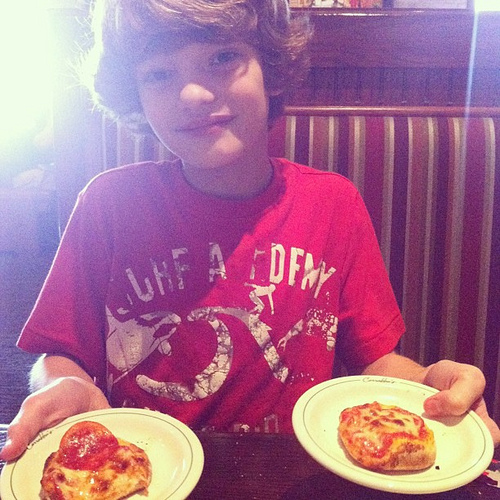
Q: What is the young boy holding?
A: Two saucers.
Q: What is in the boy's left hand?
A: A white plate.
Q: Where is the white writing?
A: On the red t-shirt.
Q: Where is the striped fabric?
A: On the back of the booth.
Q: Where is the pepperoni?
A: On the pizza.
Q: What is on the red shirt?
A: A white design with writing.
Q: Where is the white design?
A: On the t-shirt.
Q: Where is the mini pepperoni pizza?
A: On the plate.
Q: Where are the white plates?
A: In the boy's hands.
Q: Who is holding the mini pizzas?
A: The boy.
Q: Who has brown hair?
A: The boy.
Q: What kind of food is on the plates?
A: Pizza.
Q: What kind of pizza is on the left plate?
A: Pepperoni.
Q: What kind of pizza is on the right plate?
A: Cheese.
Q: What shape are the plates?
A: Round.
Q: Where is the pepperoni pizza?
A: On the left plate.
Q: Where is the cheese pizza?
A: On the right plate.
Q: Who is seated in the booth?
A: A young boy.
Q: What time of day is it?
A: Afternoon.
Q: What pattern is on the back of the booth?
A: Stripes.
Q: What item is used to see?
A: Eyes.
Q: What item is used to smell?
A: A nose.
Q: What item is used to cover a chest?
A: A shirt.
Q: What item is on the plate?
A: A pizza.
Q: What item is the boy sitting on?
A: A chair.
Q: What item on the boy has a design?
A: A shirt.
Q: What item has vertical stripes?
A: A chair.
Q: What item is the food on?
A: A plate.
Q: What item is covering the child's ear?
A: The ear.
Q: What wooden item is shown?
A: A table.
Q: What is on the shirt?
A: White writing on red shirt.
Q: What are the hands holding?
A: Hands holding white plates.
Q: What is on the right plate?
A: A mini personal cheese pizza.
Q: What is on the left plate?
A: A mini personal pepperoni pizza.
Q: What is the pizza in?
A: A small white shallow bowl with a stripe.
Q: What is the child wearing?
A: A child's red shirt with a picture of a shark and surfer.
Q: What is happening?
A: A young boy posing for a picture with two mini pizzas.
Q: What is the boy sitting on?
A: A stripped booth seat.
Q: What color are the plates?
A: White.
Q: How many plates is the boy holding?
A: Two.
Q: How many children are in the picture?
A: One.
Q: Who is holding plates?
A: The boy.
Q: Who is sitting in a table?
A: The boy.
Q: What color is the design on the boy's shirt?
A: White.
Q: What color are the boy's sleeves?
A: Red.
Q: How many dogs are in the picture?
A: Zero.